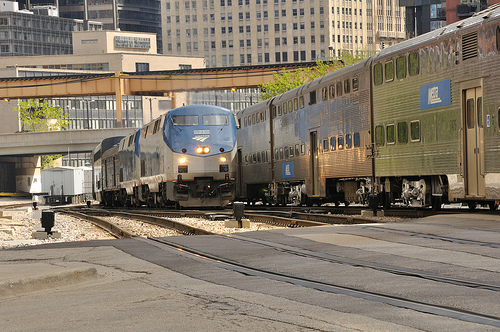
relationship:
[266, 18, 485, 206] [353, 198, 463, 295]
trains on track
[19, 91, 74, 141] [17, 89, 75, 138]
leaves on trees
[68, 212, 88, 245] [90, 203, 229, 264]
gravel by tracks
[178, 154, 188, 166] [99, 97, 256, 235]
lights of train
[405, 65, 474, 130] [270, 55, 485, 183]
sign on train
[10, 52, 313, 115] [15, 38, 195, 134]
tracks by buildings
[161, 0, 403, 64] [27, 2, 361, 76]
apartment in background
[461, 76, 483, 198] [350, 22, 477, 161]
door to train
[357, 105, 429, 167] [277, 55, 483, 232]
windows on train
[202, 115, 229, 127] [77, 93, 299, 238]
windows on train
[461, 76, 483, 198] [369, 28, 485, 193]
door on train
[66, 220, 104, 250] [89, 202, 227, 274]
pebbles next to track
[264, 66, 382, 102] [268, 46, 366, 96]
leaves on trees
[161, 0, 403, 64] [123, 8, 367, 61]
apartment in background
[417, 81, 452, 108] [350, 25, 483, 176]
sign on train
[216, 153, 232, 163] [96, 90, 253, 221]
lights on train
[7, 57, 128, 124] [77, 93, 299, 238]
wires above train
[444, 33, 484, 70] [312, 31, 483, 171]
vent of train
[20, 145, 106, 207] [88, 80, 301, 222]
building behind train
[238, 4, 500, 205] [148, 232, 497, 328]
trains on tracks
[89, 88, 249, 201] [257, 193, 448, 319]
train on tracks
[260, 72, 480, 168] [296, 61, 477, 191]
side of cars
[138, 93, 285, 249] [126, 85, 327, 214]
front on train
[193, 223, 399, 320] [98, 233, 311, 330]
tracks on road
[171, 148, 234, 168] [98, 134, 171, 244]
four lights glowing on front of blue train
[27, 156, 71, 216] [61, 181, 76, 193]
back of eighteen wheeler truck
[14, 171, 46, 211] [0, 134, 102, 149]
white back of a truck traveling under a bridge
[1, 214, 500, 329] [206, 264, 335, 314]
road with railroad tracks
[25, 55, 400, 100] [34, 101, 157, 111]
industrial buildings in photos background